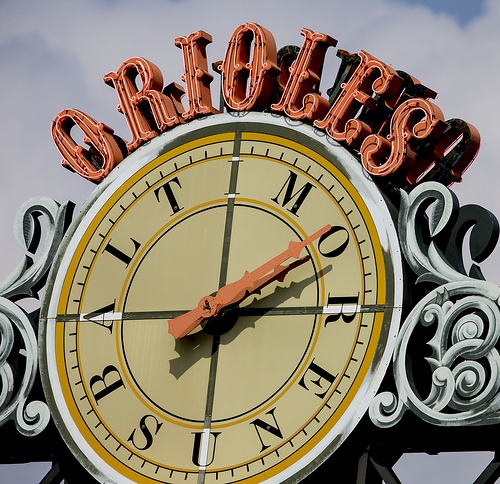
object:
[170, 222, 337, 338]
hand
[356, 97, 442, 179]
letter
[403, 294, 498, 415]
metal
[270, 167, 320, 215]
letter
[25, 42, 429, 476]
clock face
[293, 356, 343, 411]
e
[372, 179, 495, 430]
decoration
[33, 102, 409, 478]
person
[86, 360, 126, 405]
letter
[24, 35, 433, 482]
clock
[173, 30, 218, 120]
letter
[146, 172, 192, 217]
letter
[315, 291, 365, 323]
letter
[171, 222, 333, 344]
needle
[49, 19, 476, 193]
text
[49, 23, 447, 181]
orioles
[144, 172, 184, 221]
letter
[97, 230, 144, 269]
letter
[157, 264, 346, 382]
shadow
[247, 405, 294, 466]
letter